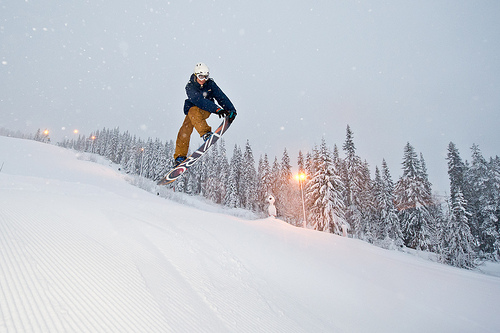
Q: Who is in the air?
A: A man.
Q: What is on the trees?
A: Snow.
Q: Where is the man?
A: In the air.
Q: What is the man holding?
A: A snowboard.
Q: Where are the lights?
A: On poles.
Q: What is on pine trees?
A: Snow.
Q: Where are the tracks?
A: In the snow.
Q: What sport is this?
A: Snowboarding.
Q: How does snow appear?
A: Tightly packed.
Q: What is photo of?
A: Snowboarder on a hill.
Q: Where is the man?
A: In the air.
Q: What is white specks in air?
A: Snow.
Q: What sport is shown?
A: Snowboarding.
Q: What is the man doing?
A: Snowboarding.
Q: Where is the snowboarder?
A: In the air.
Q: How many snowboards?
A: 1.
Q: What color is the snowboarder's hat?
A: White.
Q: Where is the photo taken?
A: Ski slope.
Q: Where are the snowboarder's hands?
A: Grabbing the board.